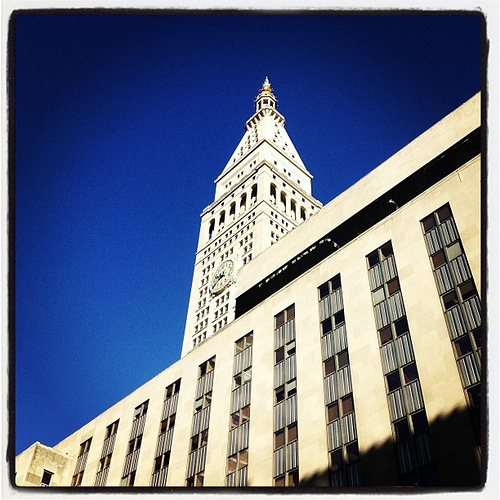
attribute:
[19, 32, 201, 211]
sky — blue, clear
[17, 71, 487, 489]
white — many , windows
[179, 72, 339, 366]
tower — big,  behind, set, corners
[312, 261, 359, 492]
windows — rectangular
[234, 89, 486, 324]
platform — black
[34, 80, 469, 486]
building — horizontal, side, tall 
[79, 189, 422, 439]
building — white